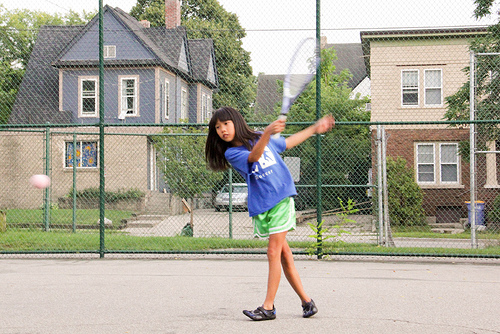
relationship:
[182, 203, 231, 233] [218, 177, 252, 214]
driveway has car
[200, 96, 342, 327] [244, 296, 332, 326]
girl wearing shoes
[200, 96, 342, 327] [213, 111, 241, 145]
girl has face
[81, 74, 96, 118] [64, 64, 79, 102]
window on wall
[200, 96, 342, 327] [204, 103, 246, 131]
girl has head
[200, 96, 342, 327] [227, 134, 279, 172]
girl has arm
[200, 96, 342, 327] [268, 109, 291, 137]
girl has hand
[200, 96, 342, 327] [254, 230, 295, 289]
girl has leg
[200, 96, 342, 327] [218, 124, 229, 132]
girl has nose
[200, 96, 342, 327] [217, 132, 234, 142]
girl has mouth